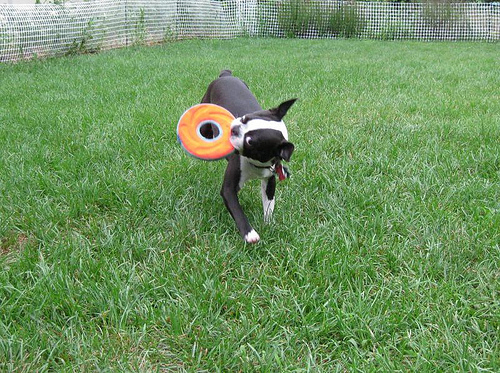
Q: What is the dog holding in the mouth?
A: Doughnut-shaped frisbee.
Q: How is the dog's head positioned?
A: Looking over right side.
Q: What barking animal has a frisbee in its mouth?
A: Dog.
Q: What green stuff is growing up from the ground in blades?
A: Grass.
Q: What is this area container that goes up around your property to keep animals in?
A: Fence.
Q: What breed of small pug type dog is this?
A: Boston Terrier.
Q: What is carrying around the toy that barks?
A: Dog.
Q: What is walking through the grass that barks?
A: Dog.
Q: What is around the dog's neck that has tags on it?
A: Collar.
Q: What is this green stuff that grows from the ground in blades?
A: Grass.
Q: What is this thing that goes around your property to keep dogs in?
A: Fence.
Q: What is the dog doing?
A: Playing.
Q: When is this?
A: Daytime.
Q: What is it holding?
A: Frisbee.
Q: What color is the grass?
A: Green.